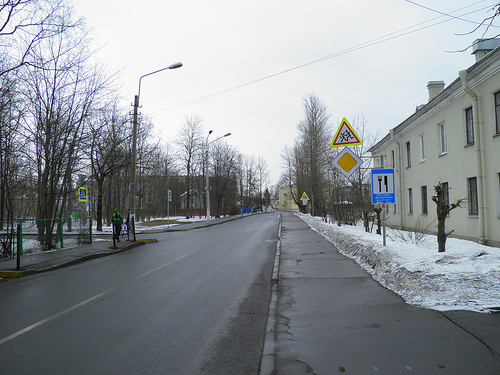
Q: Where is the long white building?
A: On the side of the road.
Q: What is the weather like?
A: Clear.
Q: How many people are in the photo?
A: Two.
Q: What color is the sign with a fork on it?
A: Blue.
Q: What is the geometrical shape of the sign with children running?
A: Triangle.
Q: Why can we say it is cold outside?
A: Snow.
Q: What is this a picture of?
A: Street.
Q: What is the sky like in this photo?
A: Overcast.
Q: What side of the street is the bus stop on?
A: Left.